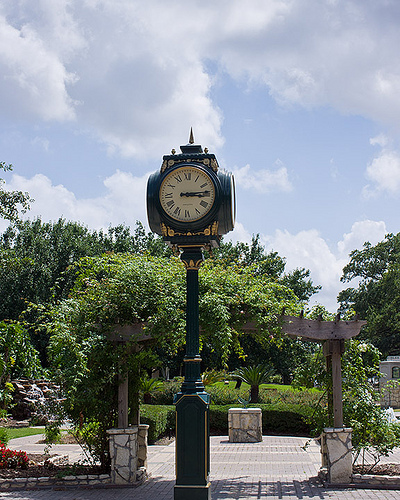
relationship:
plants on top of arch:
[16, 251, 305, 470] [119, 280, 369, 355]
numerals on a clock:
[164, 172, 212, 217] [158, 162, 218, 225]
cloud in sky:
[85, 36, 190, 121] [2, 0, 398, 322]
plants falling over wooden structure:
[75, 251, 187, 354] [95, 304, 157, 485]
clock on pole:
[155, 145, 224, 241] [171, 247, 223, 495]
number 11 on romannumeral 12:
[174, 171, 182, 186] [184, 172, 193, 180]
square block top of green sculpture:
[224, 403, 266, 444] [232, 387, 257, 408]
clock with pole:
[158, 162, 218, 225] [171, 244, 209, 499]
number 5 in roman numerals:
[185, 200, 210, 222] [141, 146, 240, 239]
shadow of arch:
[211, 474, 318, 498] [98, 305, 368, 424]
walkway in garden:
[4, 426, 397, 498] [2, 220, 396, 498]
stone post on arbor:
[101, 424, 142, 488] [97, 301, 370, 490]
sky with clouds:
[2, 0, 398, 322] [51, 22, 215, 139]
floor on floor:
[243, 455, 295, 488] [0, 407, 400, 498]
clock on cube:
[158, 162, 218, 225] [143, 118, 245, 262]